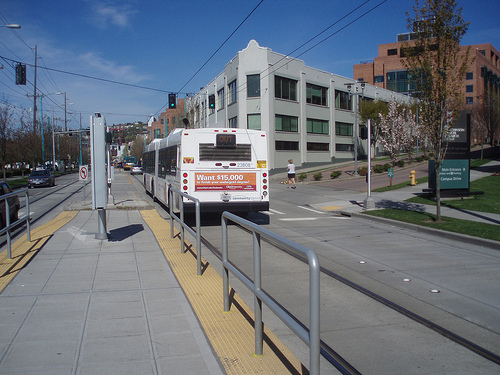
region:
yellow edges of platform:
[0, 203, 320, 374]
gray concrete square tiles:
[0, 200, 232, 373]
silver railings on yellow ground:
[0, 169, 326, 374]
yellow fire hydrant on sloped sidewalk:
[406, 168, 418, 190]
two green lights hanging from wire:
[161, 85, 220, 112]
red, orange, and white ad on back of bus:
[191, 166, 261, 198]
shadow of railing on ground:
[0, 225, 53, 285]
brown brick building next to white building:
[354, 9, 499, 159]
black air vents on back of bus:
[197, 140, 254, 163]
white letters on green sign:
[433, 153, 470, 194]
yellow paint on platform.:
[231, 319, 243, 341]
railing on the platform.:
[279, 234, 311, 258]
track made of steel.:
[419, 315, 452, 344]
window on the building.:
[307, 85, 325, 101]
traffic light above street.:
[163, 88, 175, 112]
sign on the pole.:
[72, 160, 88, 184]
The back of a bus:
[179, 127, 274, 213]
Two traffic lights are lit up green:
[163, 87, 220, 114]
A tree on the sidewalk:
[400, 1, 474, 231]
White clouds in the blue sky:
[1, 2, 498, 131]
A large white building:
[181, 37, 453, 180]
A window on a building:
[242, 69, 262, 103]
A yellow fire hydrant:
[402, 164, 422, 192]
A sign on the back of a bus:
[192, 169, 260, 195]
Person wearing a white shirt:
[282, 153, 300, 174]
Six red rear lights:
[179, 167, 272, 193]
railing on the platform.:
[282, 240, 319, 265]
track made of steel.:
[400, 310, 431, 330]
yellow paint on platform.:
[227, 329, 238, 344]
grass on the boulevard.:
[466, 225, 486, 232]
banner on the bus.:
[196, 174, 251, 189]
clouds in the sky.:
[92, 52, 136, 68]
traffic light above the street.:
[165, 90, 177, 112]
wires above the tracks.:
[322, 25, 347, 39]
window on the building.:
[305, 89, 325, 99]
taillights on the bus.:
[260, 172, 267, 201]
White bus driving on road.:
[161, 136, 296, 249]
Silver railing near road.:
[224, 215, 335, 373]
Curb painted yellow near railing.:
[161, 239, 241, 349]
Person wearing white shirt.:
[285, 162, 305, 174]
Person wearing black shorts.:
[278, 170, 317, 191]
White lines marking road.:
[272, 206, 312, 232]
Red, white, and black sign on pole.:
[71, 159, 103, 196]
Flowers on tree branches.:
[375, 108, 411, 155]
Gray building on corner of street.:
[224, 71, 312, 150]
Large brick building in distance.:
[397, 40, 468, 100]